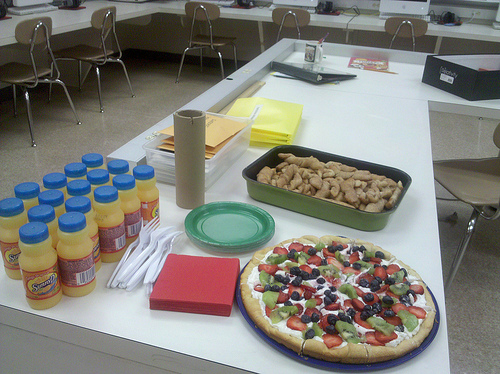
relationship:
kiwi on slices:
[262, 290, 294, 324] [245, 229, 451, 370]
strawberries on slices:
[365, 327, 395, 344] [245, 229, 451, 370]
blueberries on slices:
[362, 302, 383, 317] [245, 229, 451, 370]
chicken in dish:
[256, 147, 404, 215] [240, 138, 415, 229]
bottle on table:
[52, 208, 97, 298] [3, 48, 444, 372]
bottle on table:
[16, 222, 61, 307] [3, 48, 444, 372]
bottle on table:
[91, 187, 127, 268] [3, 48, 444, 372]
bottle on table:
[111, 172, 142, 241] [3, 48, 444, 372]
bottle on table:
[132, 160, 159, 227] [3, 48, 444, 372]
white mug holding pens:
[300, 40, 323, 69] [314, 28, 336, 42]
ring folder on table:
[276, 58, 358, 88] [3, 48, 444, 372]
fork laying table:
[136, 218, 153, 241] [16, 26, 458, 366]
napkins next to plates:
[145, 250, 241, 317] [185, 197, 275, 250]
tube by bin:
[172, 107, 209, 212] [139, 108, 254, 193]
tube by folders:
[172, 107, 209, 212] [225, 93, 302, 145]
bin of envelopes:
[139, 108, 254, 193] [154, 110, 249, 161]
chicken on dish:
[256, 147, 404, 215] [241, 143, 414, 232]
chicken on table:
[256, 147, 404, 215] [3, 48, 444, 372]